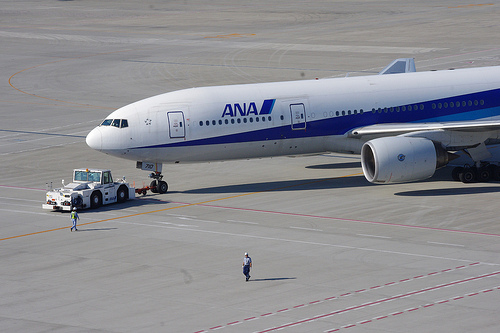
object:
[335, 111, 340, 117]
window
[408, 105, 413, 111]
window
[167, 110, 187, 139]
window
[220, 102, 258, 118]
airline name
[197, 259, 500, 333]
line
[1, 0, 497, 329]
pavement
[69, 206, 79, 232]
man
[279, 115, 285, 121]
windows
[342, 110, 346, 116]
windows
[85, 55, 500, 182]
fuselage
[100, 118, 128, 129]
windows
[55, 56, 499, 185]
plane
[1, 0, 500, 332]
runway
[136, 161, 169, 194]
landing gear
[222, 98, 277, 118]
logo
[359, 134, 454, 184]
engine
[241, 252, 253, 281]
man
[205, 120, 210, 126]
window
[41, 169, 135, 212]
truck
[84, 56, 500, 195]
airplane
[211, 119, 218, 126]
window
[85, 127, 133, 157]
nose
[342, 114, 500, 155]
wing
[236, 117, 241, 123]
window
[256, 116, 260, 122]
window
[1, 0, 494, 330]
tarmac